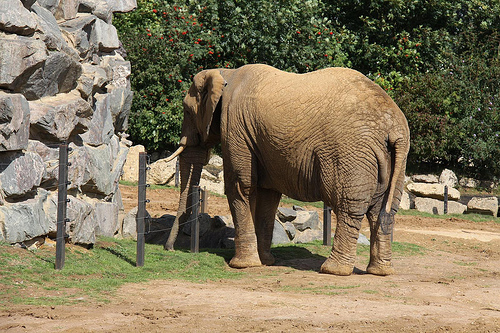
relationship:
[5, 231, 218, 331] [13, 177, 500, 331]
grass on ground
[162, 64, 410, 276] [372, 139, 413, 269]
elephant has tail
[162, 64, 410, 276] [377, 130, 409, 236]
elephant has tail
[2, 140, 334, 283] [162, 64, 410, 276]
fence in front of elephant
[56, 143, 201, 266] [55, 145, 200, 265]
hooks on post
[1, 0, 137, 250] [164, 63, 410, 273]
wall in front of elephant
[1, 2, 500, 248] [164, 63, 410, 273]
rock in front of elephant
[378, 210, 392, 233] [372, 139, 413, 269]
hair on end of tail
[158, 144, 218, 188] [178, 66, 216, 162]
tusk on face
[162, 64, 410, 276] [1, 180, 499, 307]
elephant on grass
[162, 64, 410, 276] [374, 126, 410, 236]
elephant has tail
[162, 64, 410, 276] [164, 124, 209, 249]
elephant has trunk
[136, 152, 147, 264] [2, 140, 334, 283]
pole on fence